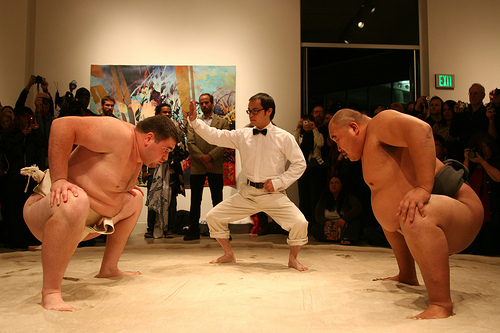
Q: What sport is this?
A: Sumo wrestling.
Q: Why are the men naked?
A: To wrestle.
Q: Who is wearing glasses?
A: The ref.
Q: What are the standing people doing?
A: Watching.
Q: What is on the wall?
A: A painting.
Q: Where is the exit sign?
A: By the door.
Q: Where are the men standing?
A: In the ring.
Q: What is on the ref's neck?
A: A tie.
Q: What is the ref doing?
A: Starting the wrestlers.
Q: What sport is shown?
A: Sumo wrestling.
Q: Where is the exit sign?
A: Right of Door.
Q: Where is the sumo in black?
A: On right.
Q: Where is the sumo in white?
A: On left.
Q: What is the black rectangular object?
A: Doorway.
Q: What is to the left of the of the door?
A: Painting.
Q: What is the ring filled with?
A: Sand.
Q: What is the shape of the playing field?
A: Circle.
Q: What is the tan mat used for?
A: Wrestling ring.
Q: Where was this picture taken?
A: In a museum.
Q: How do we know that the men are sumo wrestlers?
A: The way the men are dressed.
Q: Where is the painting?
A: On the wall.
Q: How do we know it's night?
A: It's dark outside the window.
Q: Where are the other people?
A: Behind the wrestling ring.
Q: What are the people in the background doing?
A: Watching.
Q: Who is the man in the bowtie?
A: The referee.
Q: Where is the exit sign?
A: By the door.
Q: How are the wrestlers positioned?
A: Squatting.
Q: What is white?
A: Wall.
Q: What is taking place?
A: Sumo wrestling match.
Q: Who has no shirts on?
A: Sumo wrestlers.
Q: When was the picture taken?
A: Night.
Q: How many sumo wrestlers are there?
A: Two.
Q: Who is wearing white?
A: Man in middle.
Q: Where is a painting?
A: On the wall.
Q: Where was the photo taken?
A: At a Sumo Wrestling match.